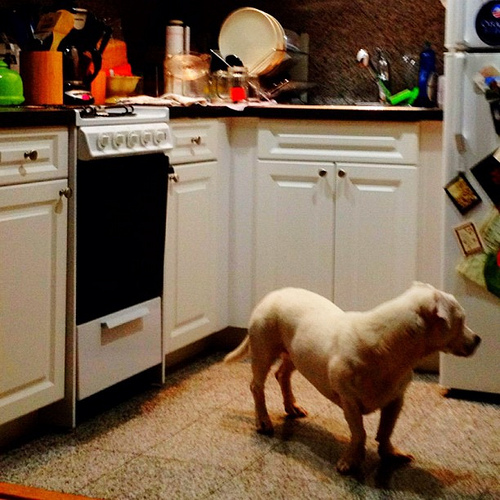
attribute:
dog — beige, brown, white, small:
[227, 279, 480, 475]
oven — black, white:
[70, 117, 171, 429]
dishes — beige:
[215, 7, 286, 78]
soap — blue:
[419, 48, 439, 107]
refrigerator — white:
[441, 0, 500, 402]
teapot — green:
[0, 62, 27, 105]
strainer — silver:
[210, 49, 317, 104]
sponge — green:
[390, 87, 420, 105]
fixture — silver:
[358, 46, 393, 104]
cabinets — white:
[167, 122, 434, 365]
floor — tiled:
[3, 346, 500, 497]